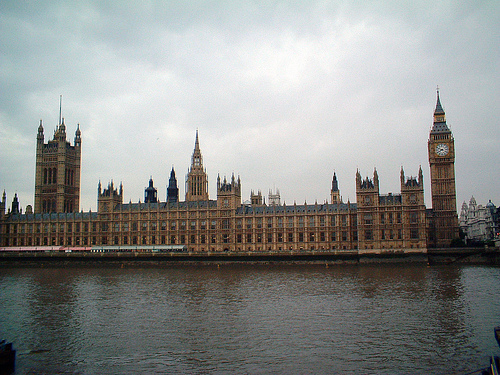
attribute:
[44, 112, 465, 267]
parliment — here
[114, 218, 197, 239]
windows — rowed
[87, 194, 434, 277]
buliding — big ben, large, stone, white, reflected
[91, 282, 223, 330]
waves — gentle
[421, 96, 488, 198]
pinnacle — sticking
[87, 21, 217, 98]
clouds — white, broken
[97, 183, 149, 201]
background — dome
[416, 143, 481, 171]
face — white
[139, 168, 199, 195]
trim — dark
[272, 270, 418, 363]
thames — infront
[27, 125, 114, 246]
tower — across, around, present, here, white, clock, by, over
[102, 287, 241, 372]
river — blue, next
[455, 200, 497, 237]
buildings — white, tall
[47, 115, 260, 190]
towers — dark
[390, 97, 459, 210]
clock tower — tall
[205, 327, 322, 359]
ripples — small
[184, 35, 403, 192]
sky — hazy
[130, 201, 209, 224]
shingles — gray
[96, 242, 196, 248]
train — going